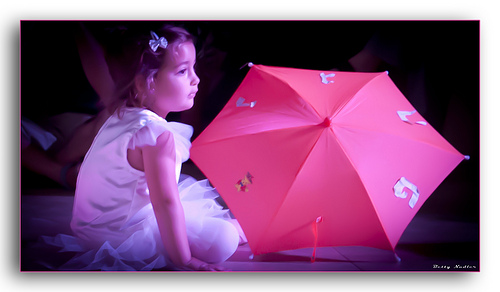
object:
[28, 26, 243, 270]
girl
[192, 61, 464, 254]
umbrella